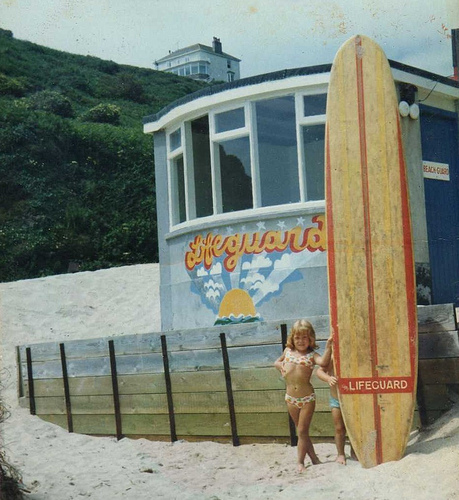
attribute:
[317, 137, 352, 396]
stripe — red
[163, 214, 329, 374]
sign — wood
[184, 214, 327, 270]
lifeguard — word, white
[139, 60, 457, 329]
house — beach house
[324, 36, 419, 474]
board — long, large, tall, wooden, surfboard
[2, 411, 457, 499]
sand — tan, white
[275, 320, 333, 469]
girl — human, small, young, little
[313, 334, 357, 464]
boy — human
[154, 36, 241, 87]
house — large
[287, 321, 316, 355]
hair — blonde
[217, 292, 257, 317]
sun — orange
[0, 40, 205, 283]
hillside — grassy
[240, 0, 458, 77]
sky — grey